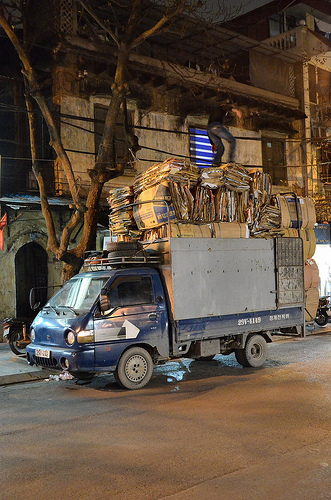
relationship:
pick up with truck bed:
[22, 229, 308, 391] [175, 274, 307, 319]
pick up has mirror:
[22, 229, 308, 391] [98, 286, 112, 311]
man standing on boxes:
[206, 97, 243, 168] [199, 162, 252, 191]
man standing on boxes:
[206, 97, 243, 168] [131, 157, 198, 190]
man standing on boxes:
[206, 97, 243, 168] [247, 166, 273, 193]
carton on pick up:
[130, 153, 202, 232] [24, 187, 308, 392]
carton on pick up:
[212, 218, 251, 236] [22, 229, 308, 391]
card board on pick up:
[133, 182, 175, 229] [22, 229, 308, 391]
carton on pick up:
[167, 222, 214, 237] [22, 229, 308, 391]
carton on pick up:
[223, 160, 249, 190] [22, 229, 308, 391]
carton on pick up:
[276, 194, 318, 227] [22, 229, 308, 391]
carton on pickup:
[261, 189, 314, 230] [21, 229, 311, 398]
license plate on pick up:
[34, 348, 48, 358] [22, 229, 308, 391]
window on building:
[187, 123, 218, 166] [1, 1, 300, 343]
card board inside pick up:
[105, 157, 317, 322] [22, 229, 308, 391]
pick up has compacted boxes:
[22, 229, 308, 391] [103, 158, 319, 324]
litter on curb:
[49, 369, 69, 384] [0, 367, 45, 385]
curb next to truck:
[0, 367, 45, 385] [18, 155, 322, 390]